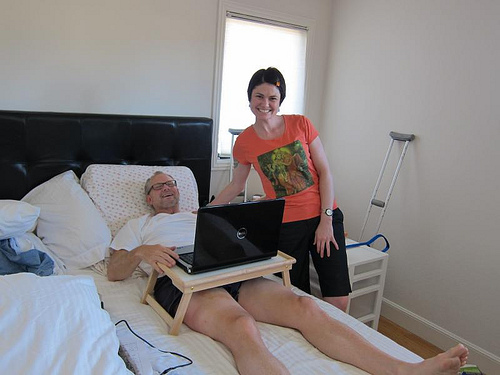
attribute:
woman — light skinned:
[215, 59, 363, 313]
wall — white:
[336, 39, 500, 168]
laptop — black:
[156, 191, 286, 271]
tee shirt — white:
[114, 202, 191, 250]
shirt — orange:
[209, 99, 344, 238]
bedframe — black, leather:
[3, 108, 215, 203]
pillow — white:
[0, 155, 203, 268]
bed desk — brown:
[150, 258, 310, 335]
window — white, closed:
[218, 5, 312, 152]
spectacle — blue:
[341, 229, 398, 254]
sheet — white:
[117, 280, 161, 364]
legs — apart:
[219, 287, 470, 373]